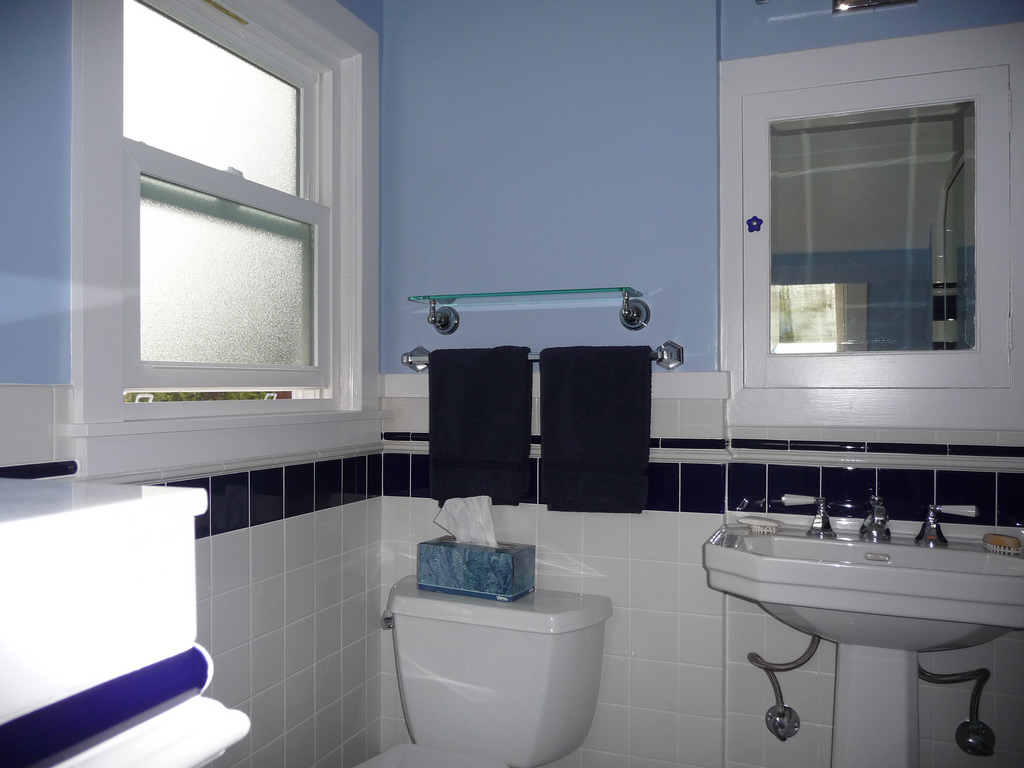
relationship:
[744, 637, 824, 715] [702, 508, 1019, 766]
pipe under sinj